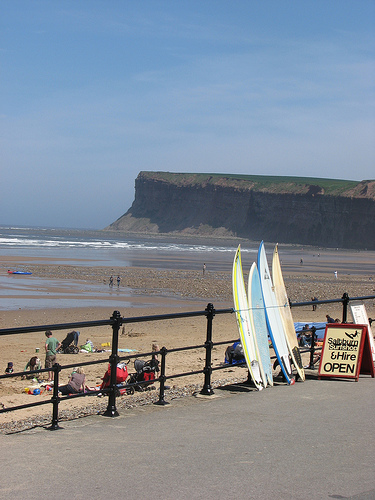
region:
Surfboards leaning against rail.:
[225, 232, 313, 392]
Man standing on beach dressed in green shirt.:
[36, 330, 68, 379]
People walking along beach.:
[103, 267, 128, 292]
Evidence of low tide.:
[81, 245, 226, 306]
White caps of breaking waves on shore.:
[17, 232, 230, 260]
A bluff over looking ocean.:
[100, 158, 331, 241]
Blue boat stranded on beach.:
[6, 267, 32, 279]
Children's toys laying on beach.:
[20, 385, 49, 402]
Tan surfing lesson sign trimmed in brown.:
[311, 314, 366, 383]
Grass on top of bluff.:
[197, 166, 362, 193]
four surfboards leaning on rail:
[225, 236, 313, 391]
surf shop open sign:
[313, 318, 369, 384]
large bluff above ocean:
[80, 167, 365, 241]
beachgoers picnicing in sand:
[0, 326, 104, 411]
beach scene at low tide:
[1, 213, 371, 409]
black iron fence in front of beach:
[1, 284, 357, 444]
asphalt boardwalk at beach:
[2, 342, 373, 499]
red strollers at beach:
[94, 335, 170, 401]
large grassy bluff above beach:
[94, 154, 370, 255]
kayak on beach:
[0, 267, 50, 288]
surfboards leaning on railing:
[227, 234, 313, 388]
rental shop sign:
[317, 320, 365, 380]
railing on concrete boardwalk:
[2, 294, 374, 402]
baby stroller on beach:
[128, 356, 157, 391]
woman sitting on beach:
[60, 365, 99, 398]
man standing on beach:
[41, 328, 63, 379]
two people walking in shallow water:
[106, 270, 125, 288]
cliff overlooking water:
[110, 163, 374, 252]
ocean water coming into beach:
[5, 226, 231, 256]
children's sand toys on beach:
[22, 378, 53, 398]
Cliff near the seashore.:
[90, 164, 365, 250]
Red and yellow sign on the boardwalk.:
[312, 311, 370, 381]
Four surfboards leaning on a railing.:
[216, 238, 310, 389]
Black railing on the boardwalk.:
[3, 314, 228, 412]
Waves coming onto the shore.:
[2, 233, 134, 252]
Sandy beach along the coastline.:
[5, 308, 93, 318]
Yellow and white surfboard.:
[222, 242, 268, 396]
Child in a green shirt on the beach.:
[37, 331, 58, 363]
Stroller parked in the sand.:
[131, 356, 159, 389]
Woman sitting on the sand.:
[63, 368, 96, 394]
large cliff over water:
[108, 159, 194, 237]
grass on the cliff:
[252, 172, 350, 206]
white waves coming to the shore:
[44, 228, 142, 252]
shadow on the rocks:
[113, 176, 235, 265]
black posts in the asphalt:
[85, 293, 153, 428]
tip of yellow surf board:
[216, 236, 254, 263]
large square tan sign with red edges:
[318, 315, 374, 381]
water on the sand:
[6, 278, 99, 320]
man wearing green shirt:
[39, 334, 63, 353]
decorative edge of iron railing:
[76, 306, 145, 334]